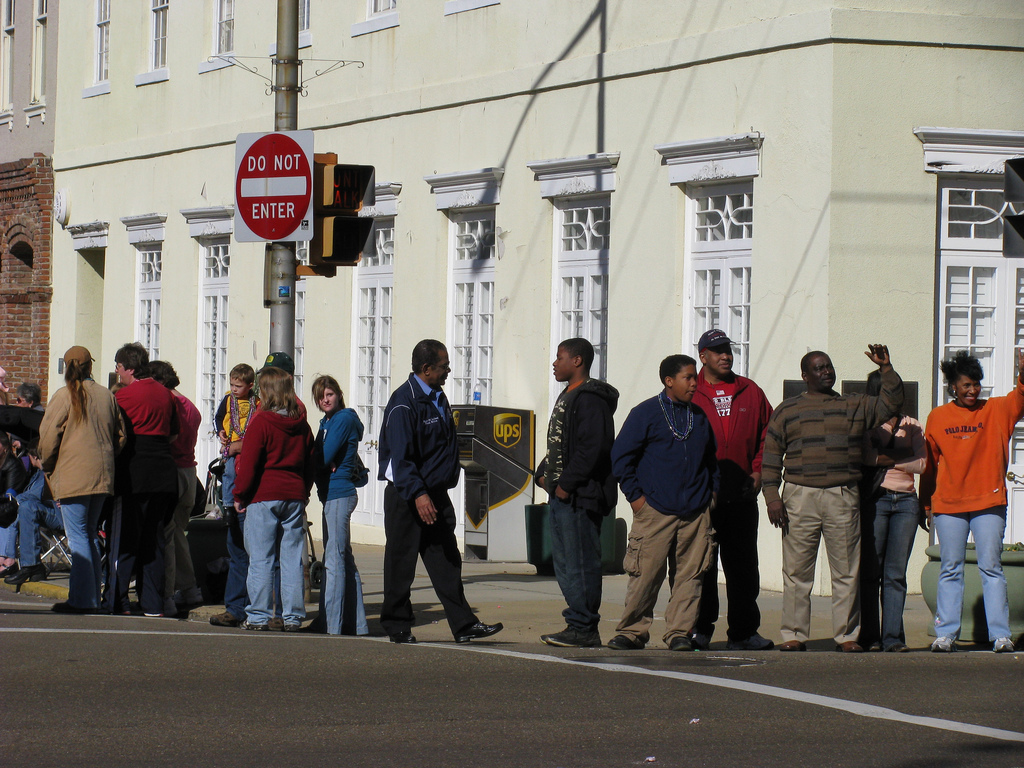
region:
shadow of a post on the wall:
[429, 4, 670, 290]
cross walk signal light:
[321, 144, 401, 300]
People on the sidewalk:
[31, 308, 1018, 613]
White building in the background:
[62, 13, 1021, 185]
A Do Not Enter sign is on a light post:
[209, 108, 432, 347]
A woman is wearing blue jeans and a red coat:
[252, 355, 336, 646]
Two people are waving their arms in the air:
[770, 332, 1001, 669]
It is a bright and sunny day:
[9, 48, 832, 763]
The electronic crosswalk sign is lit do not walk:
[324, 113, 473, 328]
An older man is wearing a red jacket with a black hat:
[694, 254, 781, 612]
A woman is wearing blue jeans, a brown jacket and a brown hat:
[32, 325, 124, 589]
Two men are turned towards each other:
[384, 323, 637, 734]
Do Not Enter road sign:
[233, 125, 316, 242]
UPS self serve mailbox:
[445, 402, 535, 562]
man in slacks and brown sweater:
[757, 339, 904, 647]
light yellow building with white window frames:
[54, 0, 1020, 595]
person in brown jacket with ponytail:
[35, 343, 119, 610]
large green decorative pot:
[919, 539, 1022, 644]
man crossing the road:
[376, 336, 504, 646]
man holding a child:
[217, 351, 287, 634]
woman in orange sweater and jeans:
[922, 348, 1022, 653]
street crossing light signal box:
[306, 146, 379, 280]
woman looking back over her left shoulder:
[309, 371, 368, 643]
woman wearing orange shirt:
[929, 399, 1012, 508]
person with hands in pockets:
[615, 454, 733, 528]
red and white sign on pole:
[233, 121, 313, 298]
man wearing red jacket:
[701, 321, 762, 461]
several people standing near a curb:
[22, 324, 1009, 664]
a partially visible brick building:
[0, 154, 58, 426]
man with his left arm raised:
[795, 324, 912, 436]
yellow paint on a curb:
[2, 561, 79, 609]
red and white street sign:
[214, 115, 355, 264]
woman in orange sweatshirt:
[898, 320, 1022, 647]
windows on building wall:
[389, 141, 786, 386]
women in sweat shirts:
[237, 343, 392, 524]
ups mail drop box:
[422, 370, 558, 598]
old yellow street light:
[299, 130, 404, 318]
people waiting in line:
[24, 311, 1023, 676]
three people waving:
[768, 318, 1022, 575]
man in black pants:
[364, 302, 507, 661]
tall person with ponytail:
[32, 329, 131, 602]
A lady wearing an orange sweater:
[929, 349, 1015, 664]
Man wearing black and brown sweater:
[751, 345, 898, 659]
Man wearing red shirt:
[694, 327, 767, 432]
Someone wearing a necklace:
[618, 354, 733, 652]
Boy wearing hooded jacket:
[514, 327, 620, 641]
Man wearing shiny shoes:
[376, 318, 509, 648]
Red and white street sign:
[204, 114, 353, 255]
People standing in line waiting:
[22, 336, 362, 632]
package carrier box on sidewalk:
[446, 378, 535, 576]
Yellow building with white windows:
[375, 19, 1023, 329]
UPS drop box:
[451, 402, 541, 567]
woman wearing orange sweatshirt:
[923, 354, 1022, 653]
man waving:
[757, 337, 917, 654]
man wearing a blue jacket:
[376, 332, 507, 646]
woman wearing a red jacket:
[224, 358, 319, 635]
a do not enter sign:
[231, 128, 315, 246]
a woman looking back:
[310, 373, 378, 636]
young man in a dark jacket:
[530, 329, 617, 656]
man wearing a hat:
[695, 327, 773, 650]